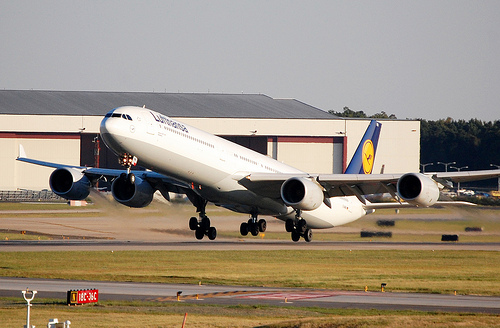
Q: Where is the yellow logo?
A: On planes tail.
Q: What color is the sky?
A: Gray.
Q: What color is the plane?
A: White and blue.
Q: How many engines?
A: Four.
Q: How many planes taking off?
A: One.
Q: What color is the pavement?
A: Gray.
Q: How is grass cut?
A: Very low.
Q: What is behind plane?
A: Hangar.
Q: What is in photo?
A: Plane and hangar.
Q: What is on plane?
A: 4 motors and wings.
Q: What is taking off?
A: Plane.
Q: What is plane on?
A: A runway.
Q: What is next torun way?
A: Wilting grass.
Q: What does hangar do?
A: Parking planes.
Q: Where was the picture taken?
A: On a runway.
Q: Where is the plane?
A: In the air.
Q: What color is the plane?
A: White.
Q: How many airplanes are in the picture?
A: One.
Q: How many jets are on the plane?
A: 4.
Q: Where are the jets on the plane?
A: Under the wings.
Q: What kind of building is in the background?
A: A hangar.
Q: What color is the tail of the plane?
A: Blue.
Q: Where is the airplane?
A: At the airport.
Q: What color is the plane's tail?
A: Blue.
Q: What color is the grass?
A: Green.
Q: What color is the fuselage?
A: White.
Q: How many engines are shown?
A: Four.